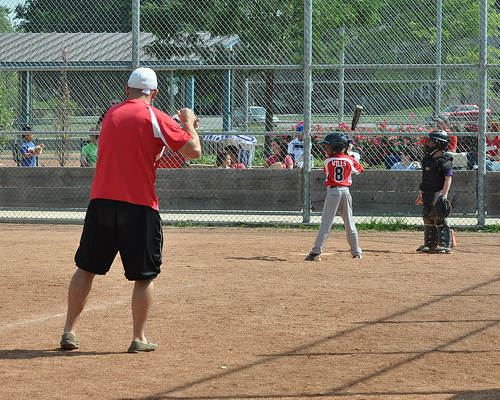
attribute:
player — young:
[297, 102, 365, 263]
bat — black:
[349, 102, 365, 136]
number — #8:
[330, 165, 347, 182]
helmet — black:
[320, 130, 349, 155]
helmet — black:
[429, 130, 456, 148]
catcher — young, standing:
[416, 127, 455, 254]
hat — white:
[125, 67, 167, 92]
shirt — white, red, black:
[321, 156, 360, 187]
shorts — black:
[81, 192, 158, 277]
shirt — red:
[104, 91, 174, 206]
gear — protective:
[423, 135, 439, 241]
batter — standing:
[296, 96, 364, 261]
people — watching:
[250, 128, 493, 164]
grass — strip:
[287, 112, 423, 121]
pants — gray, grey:
[309, 187, 361, 260]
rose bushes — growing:
[315, 120, 436, 144]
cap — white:
[129, 65, 158, 89]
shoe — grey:
[132, 334, 163, 361]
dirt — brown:
[198, 236, 495, 380]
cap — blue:
[324, 132, 349, 148]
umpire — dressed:
[412, 123, 458, 253]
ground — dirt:
[10, 228, 499, 387]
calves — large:
[72, 272, 158, 323]